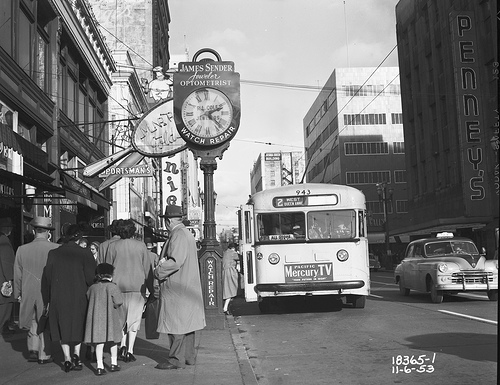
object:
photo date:
[394, 351, 436, 376]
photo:
[0, 1, 500, 381]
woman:
[220, 242, 248, 315]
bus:
[237, 183, 370, 309]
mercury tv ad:
[283, 263, 334, 285]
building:
[397, 1, 499, 262]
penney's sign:
[457, 9, 487, 204]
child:
[83, 263, 124, 375]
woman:
[41, 223, 98, 373]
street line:
[439, 309, 499, 326]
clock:
[173, 48, 241, 330]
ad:
[177, 64, 234, 88]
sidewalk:
[0, 306, 259, 384]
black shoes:
[64, 358, 72, 371]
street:
[1, 270, 499, 385]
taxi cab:
[395, 232, 499, 302]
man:
[152, 205, 206, 369]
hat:
[160, 204, 186, 219]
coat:
[43, 241, 96, 343]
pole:
[198, 156, 224, 312]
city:
[2, 0, 500, 385]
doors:
[237, 203, 255, 301]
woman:
[102, 219, 151, 361]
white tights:
[94, 341, 107, 369]